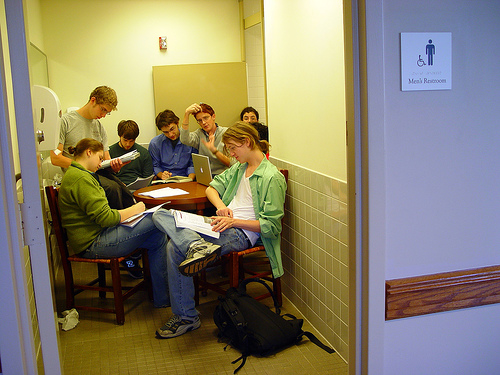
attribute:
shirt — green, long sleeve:
[193, 150, 317, 285]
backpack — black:
[181, 254, 328, 366]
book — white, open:
[139, 186, 189, 198]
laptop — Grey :
[188, 150, 215, 187]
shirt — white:
[204, 154, 285, 202]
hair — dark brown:
[151, 107, 183, 134]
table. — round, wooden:
[132, 171, 214, 208]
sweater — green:
[58, 162, 113, 252]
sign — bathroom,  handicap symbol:
[398, 28, 453, 93]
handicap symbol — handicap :
[415, 52, 427, 69]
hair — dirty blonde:
[223, 120, 273, 154]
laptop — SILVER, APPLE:
[181, 156, 261, 211]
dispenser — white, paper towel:
[31, 93, 58, 148]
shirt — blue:
[150, 133, 195, 176]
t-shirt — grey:
[55, 110, 107, 155]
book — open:
[112, 189, 239, 245]